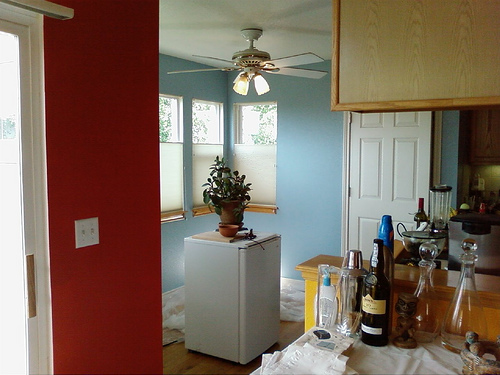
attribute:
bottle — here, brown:
[358, 241, 393, 347]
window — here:
[192, 97, 225, 215]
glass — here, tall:
[442, 238, 491, 355]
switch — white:
[73, 216, 100, 250]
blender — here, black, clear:
[430, 184, 451, 258]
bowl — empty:
[403, 231, 448, 263]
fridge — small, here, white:
[186, 228, 281, 364]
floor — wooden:
[163, 275, 304, 374]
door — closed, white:
[342, 110, 432, 262]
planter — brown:
[219, 196, 244, 229]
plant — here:
[202, 156, 253, 231]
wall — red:
[44, 2, 165, 375]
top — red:
[418, 197, 425, 211]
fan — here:
[167, 28, 328, 95]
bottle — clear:
[413, 242, 438, 345]